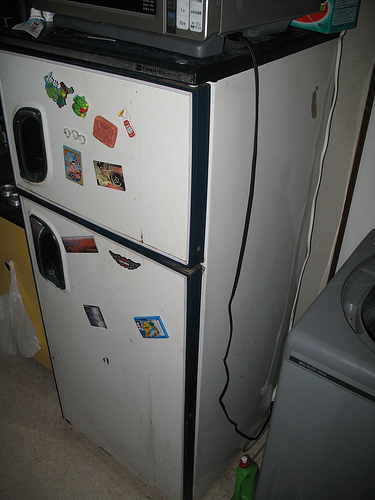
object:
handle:
[13, 105, 49, 186]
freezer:
[0, 33, 344, 498]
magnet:
[118, 104, 136, 140]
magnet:
[42, 70, 74, 109]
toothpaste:
[11, 8, 57, 40]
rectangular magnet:
[92, 157, 128, 193]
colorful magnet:
[92, 158, 128, 193]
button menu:
[188, 0, 204, 34]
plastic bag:
[0, 258, 43, 360]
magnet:
[61, 143, 83, 185]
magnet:
[82, 304, 108, 331]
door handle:
[35, 226, 57, 280]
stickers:
[70, 94, 90, 120]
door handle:
[28, 214, 67, 295]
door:
[17, 193, 188, 499]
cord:
[220, 48, 276, 441]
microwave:
[34, 2, 330, 60]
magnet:
[132, 314, 171, 339]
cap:
[240, 455, 249, 463]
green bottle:
[233, 463, 258, 498]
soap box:
[290, 0, 336, 35]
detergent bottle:
[229, 451, 261, 498]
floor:
[0, 349, 272, 499]